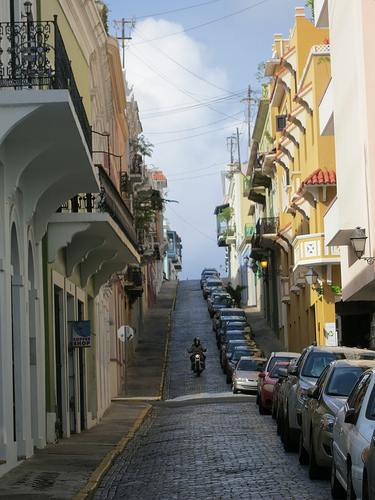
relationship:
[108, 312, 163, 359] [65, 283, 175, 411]
sign for shop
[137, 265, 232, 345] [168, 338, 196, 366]
road has surface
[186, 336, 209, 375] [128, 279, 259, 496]
motorcycle on street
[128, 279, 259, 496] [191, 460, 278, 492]
street made of cobbletsones